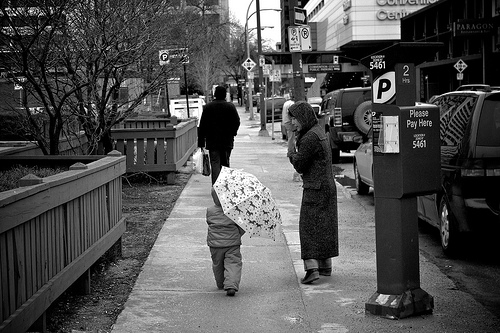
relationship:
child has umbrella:
[206, 187, 246, 297] [213, 166, 285, 240]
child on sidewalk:
[206, 187, 246, 297] [144, 290, 207, 331]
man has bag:
[197, 85, 247, 181] [197, 152, 214, 177]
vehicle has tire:
[319, 85, 374, 165] [353, 99, 376, 134]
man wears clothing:
[197, 85, 240, 187] [203, 101, 237, 162]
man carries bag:
[197, 85, 240, 187] [192, 140, 215, 177]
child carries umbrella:
[206, 187, 246, 297] [211, 162, 285, 242]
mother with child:
[286, 104, 342, 281] [206, 188, 248, 293]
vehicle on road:
[319, 87, 371, 164] [451, 241, 498, 304]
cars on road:
[353, 84, 500, 259] [451, 241, 498, 304]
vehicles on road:
[248, 82, 285, 122] [451, 241, 498, 304]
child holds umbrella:
[205, 187, 242, 297] [211, 162, 285, 242]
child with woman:
[206, 187, 246, 297] [283, 98, 335, 282]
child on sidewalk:
[206, 187, 246, 297] [117, 82, 488, 321]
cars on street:
[353, 84, 500, 259] [260, 62, 497, 300]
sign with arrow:
[287, 22, 326, 54] [285, 33, 303, 45]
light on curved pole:
[243, 4, 262, 126] [240, 3, 291, 118]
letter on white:
[376, 78, 391, 100] [244, 3, 287, 20]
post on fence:
[104, 147, 121, 159] [2, 150, 128, 332]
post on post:
[104, 147, 121, 159] [68, 160, 90, 169]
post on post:
[104, 147, 121, 159] [19, 172, 41, 184]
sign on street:
[370, 71, 399, 107] [308, 86, 483, 268]